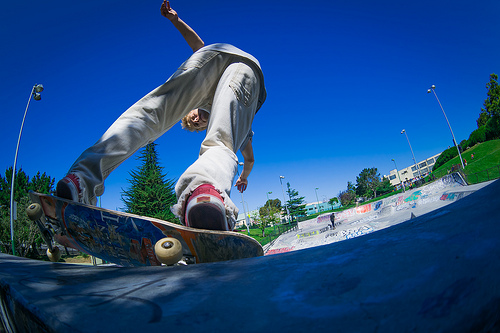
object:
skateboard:
[26, 191, 264, 266]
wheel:
[154, 236, 183, 264]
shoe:
[184, 183, 229, 231]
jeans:
[67, 50, 262, 231]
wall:
[0, 180, 497, 332]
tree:
[118, 142, 181, 224]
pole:
[431, 89, 464, 169]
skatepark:
[2, 171, 500, 330]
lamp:
[427, 85, 435, 94]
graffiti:
[403, 190, 422, 203]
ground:
[0, 170, 498, 333]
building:
[380, 153, 440, 188]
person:
[330, 213, 336, 230]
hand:
[160, 0, 178, 20]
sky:
[1, 2, 498, 211]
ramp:
[0, 178, 497, 333]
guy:
[57, 0, 267, 232]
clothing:
[330, 215, 335, 228]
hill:
[423, 139, 499, 185]